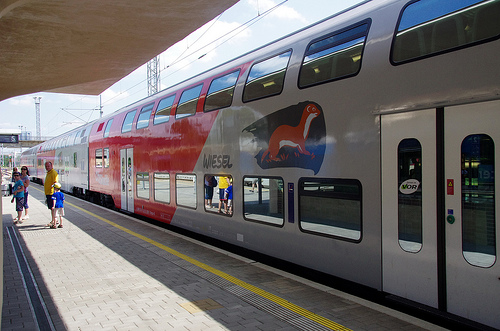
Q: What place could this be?
A: It is a sidewalk.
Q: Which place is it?
A: It is a sidewalk.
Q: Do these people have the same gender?
A: No, they are both male and female.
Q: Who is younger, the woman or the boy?
A: The boy is younger than the woman.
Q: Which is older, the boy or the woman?
A: The woman is older than the boy.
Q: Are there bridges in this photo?
A: Yes, there is a bridge.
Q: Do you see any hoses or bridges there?
A: Yes, there is a bridge.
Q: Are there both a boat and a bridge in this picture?
A: No, there is a bridge but no boats.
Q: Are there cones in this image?
A: No, there are no cones.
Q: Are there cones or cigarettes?
A: No, there are no cones or cigarettes.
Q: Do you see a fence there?
A: No, there are no fences.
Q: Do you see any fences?
A: No, there are no fences.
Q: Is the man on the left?
A: Yes, the man is on the left of the image.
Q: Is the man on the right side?
A: No, the man is on the left of the image.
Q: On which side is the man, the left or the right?
A: The man is on the left of the image.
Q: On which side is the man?
A: The man is on the left of the image.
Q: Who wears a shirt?
A: The man wears a shirt.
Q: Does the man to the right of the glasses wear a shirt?
A: Yes, the man wears a shirt.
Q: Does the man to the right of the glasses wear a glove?
A: No, the man wears a shirt.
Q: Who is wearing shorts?
A: The man is wearing shorts.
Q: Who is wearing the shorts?
A: The man is wearing shorts.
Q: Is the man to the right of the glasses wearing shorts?
A: Yes, the man is wearing shorts.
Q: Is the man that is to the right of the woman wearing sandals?
A: No, the man is wearing shorts.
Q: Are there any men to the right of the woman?
A: Yes, there is a man to the right of the woman.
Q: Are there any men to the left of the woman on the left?
A: No, the man is to the right of the woman.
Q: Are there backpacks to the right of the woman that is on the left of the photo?
A: No, there is a man to the right of the woman.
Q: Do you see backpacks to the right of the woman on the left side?
A: No, there is a man to the right of the woman.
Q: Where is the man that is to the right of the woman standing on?
A: The man is standing on the sidewalk.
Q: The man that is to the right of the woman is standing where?
A: The man is standing on the sidewalk.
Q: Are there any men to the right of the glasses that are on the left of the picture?
A: Yes, there is a man to the right of the glasses.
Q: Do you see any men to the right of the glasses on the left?
A: Yes, there is a man to the right of the glasses.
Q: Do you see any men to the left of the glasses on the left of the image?
A: No, the man is to the right of the glasses.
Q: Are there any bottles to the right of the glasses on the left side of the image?
A: No, there is a man to the right of the glasses.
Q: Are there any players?
A: No, there are no players.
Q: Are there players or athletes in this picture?
A: No, there are no players or athletes.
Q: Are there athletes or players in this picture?
A: No, there are no players or athletes.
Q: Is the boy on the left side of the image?
A: Yes, the boy is on the left of the image.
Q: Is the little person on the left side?
A: Yes, the boy is on the left of the image.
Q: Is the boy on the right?
A: No, the boy is on the left of the image.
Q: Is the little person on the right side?
A: No, the boy is on the left of the image.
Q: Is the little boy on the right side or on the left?
A: The boy is on the left of the image.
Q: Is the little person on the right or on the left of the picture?
A: The boy is on the left of the image.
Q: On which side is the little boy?
A: The boy is on the left of the image.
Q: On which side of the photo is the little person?
A: The boy is on the left of the image.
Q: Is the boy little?
A: Yes, the boy is little.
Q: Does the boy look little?
A: Yes, the boy is little.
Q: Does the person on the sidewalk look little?
A: Yes, the boy is little.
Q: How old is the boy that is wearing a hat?
A: The boy is little.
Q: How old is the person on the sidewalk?
A: The boy is little.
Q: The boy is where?
A: The boy is on the sidewalk.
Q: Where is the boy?
A: The boy is on the sidewalk.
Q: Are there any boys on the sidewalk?
A: Yes, there is a boy on the sidewalk.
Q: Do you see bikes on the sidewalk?
A: No, there is a boy on the sidewalk.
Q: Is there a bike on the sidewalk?
A: No, there is a boy on the sidewalk.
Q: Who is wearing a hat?
A: The boy is wearing a hat.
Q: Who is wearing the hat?
A: The boy is wearing a hat.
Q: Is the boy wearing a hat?
A: Yes, the boy is wearing a hat.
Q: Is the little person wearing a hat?
A: Yes, the boy is wearing a hat.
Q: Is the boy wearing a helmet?
A: No, the boy is wearing a hat.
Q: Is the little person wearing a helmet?
A: No, the boy is wearing a hat.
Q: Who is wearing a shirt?
A: The boy is wearing a shirt.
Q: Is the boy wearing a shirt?
A: Yes, the boy is wearing a shirt.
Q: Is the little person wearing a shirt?
A: Yes, the boy is wearing a shirt.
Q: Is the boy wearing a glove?
A: No, the boy is wearing a shirt.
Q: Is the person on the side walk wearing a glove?
A: No, the boy is wearing a shirt.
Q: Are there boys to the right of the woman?
A: Yes, there is a boy to the right of the woman.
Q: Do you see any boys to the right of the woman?
A: Yes, there is a boy to the right of the woman.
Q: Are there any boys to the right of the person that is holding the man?
A: Yes, there is a boy to the right of the woman.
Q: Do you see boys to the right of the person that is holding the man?
A: Yes, there is a boy to the right of the woman.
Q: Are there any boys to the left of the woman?
A: No, the boy is to the right of the woman.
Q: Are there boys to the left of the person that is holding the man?
A: No, the boy is to the right of the woman.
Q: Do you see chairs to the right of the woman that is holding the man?
A: No, there is a boy to the right of the woman.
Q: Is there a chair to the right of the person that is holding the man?
A: No, there is a boy to the right of the woman.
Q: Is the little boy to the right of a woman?
A: Yes, the boy is to the right of a woman.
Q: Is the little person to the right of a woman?
A: Yes, the boy is to the right of a woman.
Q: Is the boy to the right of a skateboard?
A: No, the boy is to the right of a woman.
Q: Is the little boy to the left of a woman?
A: No, the boy is to the right of a woman.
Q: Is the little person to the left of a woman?
A: No, the boy is to the right of a woman.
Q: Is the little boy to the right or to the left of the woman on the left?
A: The boy is to the right of the woman.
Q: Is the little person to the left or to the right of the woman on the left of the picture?
A: The boy is to the right of the woman.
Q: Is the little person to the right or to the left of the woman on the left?
A: The boy is to the right of the woman.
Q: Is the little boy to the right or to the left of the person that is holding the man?
A: The boy is to the right of the woman.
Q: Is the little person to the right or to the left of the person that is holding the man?
A: The boy is to the right of the woman.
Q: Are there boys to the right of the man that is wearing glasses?
A: Yes, there is a boy to the right of the man.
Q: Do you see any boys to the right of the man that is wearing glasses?
A: Yes, there is a boy to the right of the man.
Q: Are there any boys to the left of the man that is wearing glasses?
A: No, the boy is to the right of the man.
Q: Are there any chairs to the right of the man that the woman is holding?
A: No, there is a boy to the right of the man.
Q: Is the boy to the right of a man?
A: Yes, the boy is to the right of a man.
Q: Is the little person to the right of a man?
A: Yes, the boy is to the right of a man.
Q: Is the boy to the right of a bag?
A: No, the boy is to the right of a man.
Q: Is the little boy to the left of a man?
A: No, the boy is to the right of a man.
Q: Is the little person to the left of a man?
A: No, the boy is to the right of a man.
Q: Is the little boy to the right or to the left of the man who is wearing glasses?
A: The boy is to the right of the man.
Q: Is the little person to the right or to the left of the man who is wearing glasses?
A: The boy is to the right of the man.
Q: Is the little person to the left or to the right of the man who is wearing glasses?
A: The boy is to the right of the man.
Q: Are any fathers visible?
A: No, there are no fathers.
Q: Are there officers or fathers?
A: No, there are no fathers or officers.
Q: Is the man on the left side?
A: Yes, the man is on the left of the image.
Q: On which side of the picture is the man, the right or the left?
A: The man is on the left of the image.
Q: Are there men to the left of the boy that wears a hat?
A: Yes, there is a man to the left of the boy.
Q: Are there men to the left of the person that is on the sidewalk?
A: Yes, there is a man to the left of the boy.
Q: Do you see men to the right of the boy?
A: No, the man is to the left of the boy.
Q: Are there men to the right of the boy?
A: No, the man is to the left of the boy.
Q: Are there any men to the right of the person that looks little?
A: No, the man is to the left of the boy.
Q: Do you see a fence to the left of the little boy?
A: No, there is a man to the left of the boy.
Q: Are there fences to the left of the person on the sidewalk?
A: No, there is a man to the left of the boy.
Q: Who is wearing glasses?
A: The man is wearing glasses.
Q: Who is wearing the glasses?
A: The man is wearing glasses.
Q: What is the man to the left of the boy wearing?
A: The man is wearing glasses.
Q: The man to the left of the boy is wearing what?
A: The man is wearing glasses.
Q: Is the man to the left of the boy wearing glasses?
A: Yes, the man is wearing glasses.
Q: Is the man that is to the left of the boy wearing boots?
A: No, the man is wearing glasses.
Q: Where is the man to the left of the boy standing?
A: The man is standing on the sidewalk.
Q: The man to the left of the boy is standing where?
A: The man is standing on the sidewalk.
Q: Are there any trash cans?
A: No, there are no trash cans.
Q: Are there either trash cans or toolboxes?
A: No, there are no trash cans or toolboxes.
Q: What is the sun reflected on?
A: The sun is reflected on the sidewalk.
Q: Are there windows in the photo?
A: Yes, there is a window.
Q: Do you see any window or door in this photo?
A: Yes, there is a window.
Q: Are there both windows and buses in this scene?
A: No, there is a window but no buses.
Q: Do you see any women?
A: Yes, there is a woman.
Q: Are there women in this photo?
A: Yes, there is a woman.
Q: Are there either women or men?
A: Yes, there is a woman.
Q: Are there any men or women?
A: Yes, there is a woman.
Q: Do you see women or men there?
A: Yes, there is a woman.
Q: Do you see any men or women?
A: Yes, there is a woman.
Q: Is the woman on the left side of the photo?
A: Yes, the woman is on the left of the image.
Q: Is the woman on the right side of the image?
A: No, the woman is on the left of the image.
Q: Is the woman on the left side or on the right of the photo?
A: The woman is on the left of the image.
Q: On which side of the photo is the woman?
A: The woman is on the left of the image.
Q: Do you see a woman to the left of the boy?
A: Yes, there is a woman to the left of the boy.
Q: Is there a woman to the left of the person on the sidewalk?
A: Yes, there is a woman to the left of the boy.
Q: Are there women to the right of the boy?
A: No, the woman is to the left of the boy.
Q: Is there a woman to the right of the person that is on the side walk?
A: No, the woman is to the left of the boy.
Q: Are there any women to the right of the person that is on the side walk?
A: No, the woman is to the left of the boy.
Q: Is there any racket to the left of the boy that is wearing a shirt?
A: No, there is a woman to the left of the boy.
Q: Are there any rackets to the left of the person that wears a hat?
A: No, there is a woman to the left of the boy.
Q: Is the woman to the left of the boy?
A: Yes, the woman is to the left of the boy.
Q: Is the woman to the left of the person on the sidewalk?
A: Yes, the woman is to the left of the boy.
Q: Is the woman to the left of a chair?
A: No, the woman is to the left of the boy.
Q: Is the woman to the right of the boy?
A: No, the woman is to the left of the boy.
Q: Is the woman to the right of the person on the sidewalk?
A: No, the woman is to the left of the boy.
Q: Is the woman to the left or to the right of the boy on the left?
A: The woman is to the left of the boy.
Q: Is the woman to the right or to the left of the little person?
A: The woman is to the left of the boy.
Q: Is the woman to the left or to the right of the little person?
A: The woman is to the left of the boy.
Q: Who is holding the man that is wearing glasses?
A: The woman is holding the man.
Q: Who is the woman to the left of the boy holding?
A: The woman is holding the man.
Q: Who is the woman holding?
A: The woman is holding the man.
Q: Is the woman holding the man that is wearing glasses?
A: Yes, the woman is holding the man.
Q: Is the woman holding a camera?
A: No, the woman is holding the man.